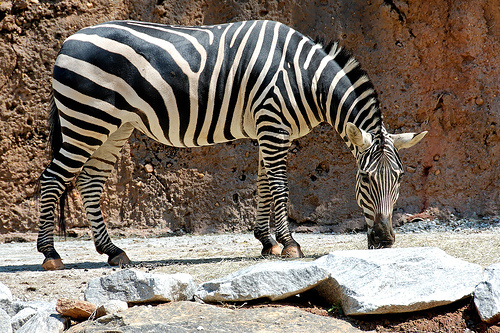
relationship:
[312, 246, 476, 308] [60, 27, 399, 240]
rocks in front of zebra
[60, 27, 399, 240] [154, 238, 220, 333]
zebra on dirt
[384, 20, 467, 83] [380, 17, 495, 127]
wall of stone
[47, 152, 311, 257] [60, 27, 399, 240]
legs of zebra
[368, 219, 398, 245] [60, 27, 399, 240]
nose of zebra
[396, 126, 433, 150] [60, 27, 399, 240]
ear of zebra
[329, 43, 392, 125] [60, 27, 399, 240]
mane of zebra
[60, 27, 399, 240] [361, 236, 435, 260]
zebra leaning to eat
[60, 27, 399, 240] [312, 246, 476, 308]
zebra behind rocks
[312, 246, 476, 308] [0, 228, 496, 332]
rocks on ground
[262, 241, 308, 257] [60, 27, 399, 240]
hooves of zebra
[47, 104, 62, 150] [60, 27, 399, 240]
tail of zebra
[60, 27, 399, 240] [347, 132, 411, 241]
zebra has headdown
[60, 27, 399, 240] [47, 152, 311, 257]
zebra has fourlegs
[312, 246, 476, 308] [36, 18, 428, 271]
rocks in front of zebra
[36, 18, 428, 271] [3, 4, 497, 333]
zebra at zoo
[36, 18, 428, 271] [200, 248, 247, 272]
zebra eating grass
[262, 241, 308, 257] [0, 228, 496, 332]
hooves on ground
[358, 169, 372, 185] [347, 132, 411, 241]
eyes in face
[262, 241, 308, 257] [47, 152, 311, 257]
hooves on legs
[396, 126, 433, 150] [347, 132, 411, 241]
ears on head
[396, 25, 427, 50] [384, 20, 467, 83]
holes on wall